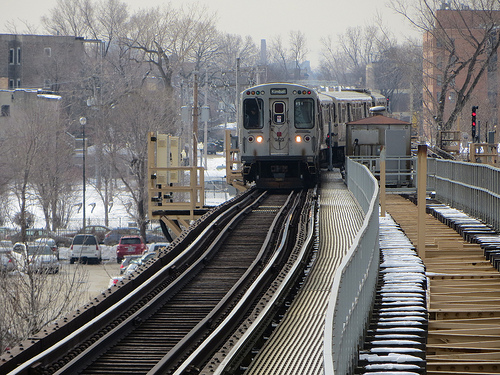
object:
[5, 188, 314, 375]
tracks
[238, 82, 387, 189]
train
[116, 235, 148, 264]
vehicle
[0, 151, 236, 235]
snow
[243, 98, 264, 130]
window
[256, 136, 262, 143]
light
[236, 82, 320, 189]
front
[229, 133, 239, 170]
spoke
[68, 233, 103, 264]
suv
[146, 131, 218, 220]
post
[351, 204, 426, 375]
platform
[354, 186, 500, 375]
walkway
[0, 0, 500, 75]
sky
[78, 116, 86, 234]
pole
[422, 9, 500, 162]
building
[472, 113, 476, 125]
light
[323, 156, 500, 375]
fence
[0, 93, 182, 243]
trees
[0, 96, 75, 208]
leaves